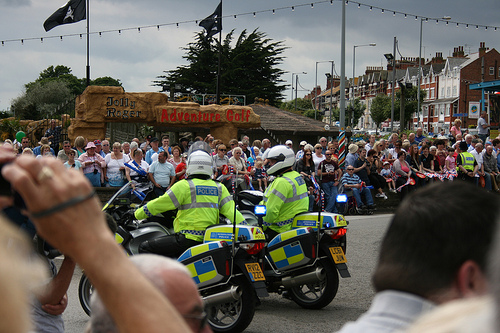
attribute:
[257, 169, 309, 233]
jacket — bright green, light green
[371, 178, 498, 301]
hair — short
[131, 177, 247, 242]
jacket — bright green, green, light green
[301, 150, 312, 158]
sunglasses — dark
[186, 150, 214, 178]
helmet — white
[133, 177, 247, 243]
coat — green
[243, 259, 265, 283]
license — black, yellow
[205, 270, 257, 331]
wheel — black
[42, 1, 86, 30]
flag — black, white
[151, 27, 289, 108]
pines — green, distant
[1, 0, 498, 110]
sky — gray, white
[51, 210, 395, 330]
concrete — grey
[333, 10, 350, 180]
pole — GREY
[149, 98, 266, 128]
sign — RED, BROWN, MINI GOLF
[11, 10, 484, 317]
picture — RAINY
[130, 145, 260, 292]
officer — POLICE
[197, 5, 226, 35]
flag — BLACK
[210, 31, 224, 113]
pole — BLACK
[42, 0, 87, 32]
flag — black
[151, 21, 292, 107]
tree — big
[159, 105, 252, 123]
sign — red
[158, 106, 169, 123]
letter — red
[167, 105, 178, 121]
letter — red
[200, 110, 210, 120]
letter — red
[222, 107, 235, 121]
letter — red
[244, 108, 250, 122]
letter — red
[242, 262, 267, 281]
license plate — yellow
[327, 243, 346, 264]
license plate — yellow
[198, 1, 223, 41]
flag — black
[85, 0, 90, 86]
flag pole — metal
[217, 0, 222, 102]
flag pole — metal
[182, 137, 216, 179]
helmet — white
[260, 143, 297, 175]
helmet — white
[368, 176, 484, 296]
hair — short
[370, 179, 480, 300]
hair — brown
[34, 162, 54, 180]
ring — gold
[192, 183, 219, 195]
patch — square, blue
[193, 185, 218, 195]
font — gray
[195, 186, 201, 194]
letter — uppercase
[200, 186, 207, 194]
letter — uppercase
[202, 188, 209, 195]
letter — uppercase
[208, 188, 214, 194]
letter — uppercase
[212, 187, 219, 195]
letter — uppercase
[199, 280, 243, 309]
tailpipe — long, cylindrical, silver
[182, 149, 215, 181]
helmet — white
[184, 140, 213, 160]
visor — transparent, plastic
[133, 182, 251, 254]
jacket — neon lime, hazard jacket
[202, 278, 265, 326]
wheel — firm, pressurized, motorcycle wheel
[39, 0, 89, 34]
flag — unfurled, black, flapping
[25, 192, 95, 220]
strap — lanyard, tight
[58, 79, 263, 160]
stone — brown, faux